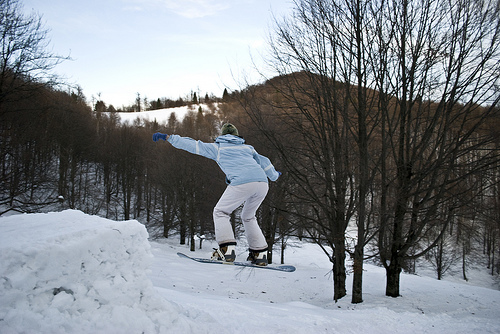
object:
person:
[153, 124, 285, 265]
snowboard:
[172, 249, 298, 272]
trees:
[271, 0, 499, 304]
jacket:
[165, 131, 282, 185]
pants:
[211, 180, 270, 252]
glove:
[151, 131, 168, 141]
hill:
[0, 69, 500, 277]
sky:
[2, 1, 499, 111]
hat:
[219, 121, 240, 137]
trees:
[0, 1, 62, 216]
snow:
[1, 212, 499, 333]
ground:
[0, 203, 500, 333]